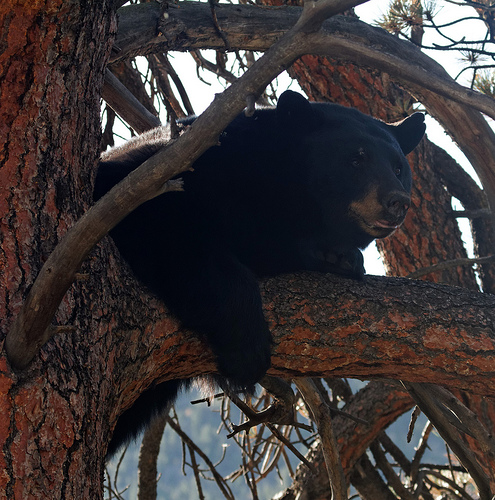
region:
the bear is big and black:
[104, 78, 425, 373]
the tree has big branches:
[16, 23, 164, 484]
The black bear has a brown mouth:
[353, 188, 412, 228]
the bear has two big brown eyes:
[344, 157, 408, 169]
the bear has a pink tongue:
[374, 214, 406, 222]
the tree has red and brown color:
[15, 305, 157, 486]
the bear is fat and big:
[173, 87, 416, 364]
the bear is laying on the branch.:
[95, 99, 444, 371]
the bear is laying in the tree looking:
[113, 90, 423, 372]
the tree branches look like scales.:
[4, 210, 116, 489]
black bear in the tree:
[52, 73, 435, 396]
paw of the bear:
[171, 291, 280, 389]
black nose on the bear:
[378, 189, 413, 223]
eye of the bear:
[342, 142, 370, 172]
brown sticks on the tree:
[227, 395, 304, 459]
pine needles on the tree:
[369, 4, 408, 40]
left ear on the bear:
[267, 85, 317, 136]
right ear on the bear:
[379, 107, 436, 153]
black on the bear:
[210, 184, 260, 239]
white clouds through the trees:
[178, 399, 222, 457]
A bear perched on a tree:
[191, 91, 430, 283]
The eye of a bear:
[352, 161, 360, 169]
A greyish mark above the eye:
[358, 151, 363, 155]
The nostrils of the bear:
[390, 201, 408, 210]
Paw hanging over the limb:
[228, 363, 264, 380]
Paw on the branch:
[310, 240, 362, 273]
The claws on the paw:
[320, 257, 355, 268]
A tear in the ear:
[421, 116, 426, 125]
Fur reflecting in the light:
[198, 379, 211, 391]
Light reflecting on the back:
[134, 134, 158, 143]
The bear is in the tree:
[104, 90, 492, 333]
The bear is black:
[67, 88, 441, 376]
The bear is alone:
[79, 84, 447, 396]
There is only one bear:
[58, 81, 463, 394]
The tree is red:
[6, 5, 469, 385]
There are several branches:
[111, 382, 386, 498]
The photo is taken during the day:
[5, 8, 453, 248]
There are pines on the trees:
[361, 5, 493, 68]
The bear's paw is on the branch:
[94, 203, 318, 403]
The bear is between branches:
[101, 99, 467, 321]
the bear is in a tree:
[99, 94, 429, 378]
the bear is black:
[102, 89, 423, 389]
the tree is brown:
[1, 0, 491, 497]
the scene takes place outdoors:
[0, 0, 492, 497]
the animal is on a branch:
[97, 94, 422, 390]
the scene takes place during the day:
[2, 0, 492, 497]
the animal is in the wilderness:
[0, 2, 492, 497]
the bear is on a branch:
[104, 96, 424, 388]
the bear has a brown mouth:
[357, 188, 402, 241]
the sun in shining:
[103, 379, 466, 496]